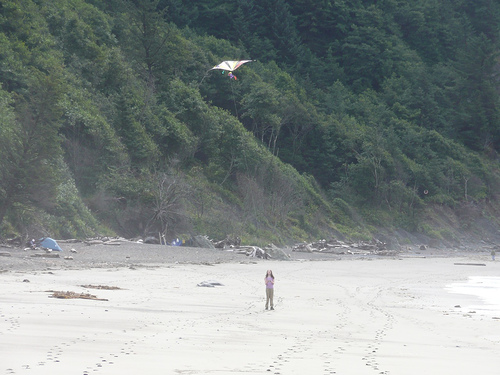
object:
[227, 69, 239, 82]
tail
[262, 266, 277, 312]
girl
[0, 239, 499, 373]
beach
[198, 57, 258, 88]
kite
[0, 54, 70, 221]
trees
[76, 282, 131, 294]
seaweeds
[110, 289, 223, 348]
sand